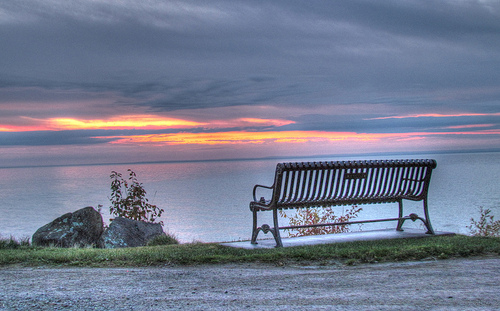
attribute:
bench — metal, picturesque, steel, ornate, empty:
[251, 159, 438, 250]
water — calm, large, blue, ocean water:
[2, 151, 497, 243]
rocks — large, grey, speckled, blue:
[32, 206, 164, 251]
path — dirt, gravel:
[2, 253, 499, 310]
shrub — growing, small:
[279, 205, 364, 239]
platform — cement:
[220, 228, 455, 251]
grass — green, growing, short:
[3, 234, 180, 269]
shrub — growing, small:
[465, 207, 499, 237]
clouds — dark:
[3, 2, 493, 146]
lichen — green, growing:
[103, 223, 130, 249]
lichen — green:
[44, 217, 129, 251]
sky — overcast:
[0, 2, 497, 142]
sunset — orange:
[0, 112, 498, 149]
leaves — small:
[95, 168, 165, 227]